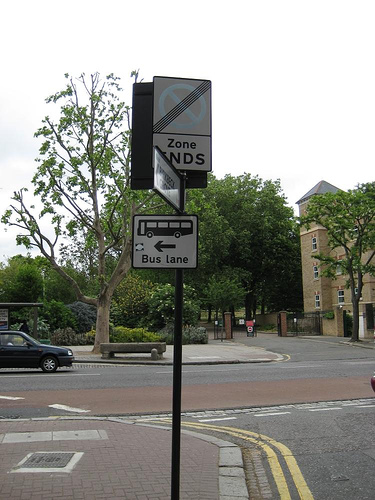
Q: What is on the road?
A: A car.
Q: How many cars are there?
A: 1.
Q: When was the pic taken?
A: During the day.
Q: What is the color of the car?
A: Black.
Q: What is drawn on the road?
A: Lines.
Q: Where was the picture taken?
A: On the street.